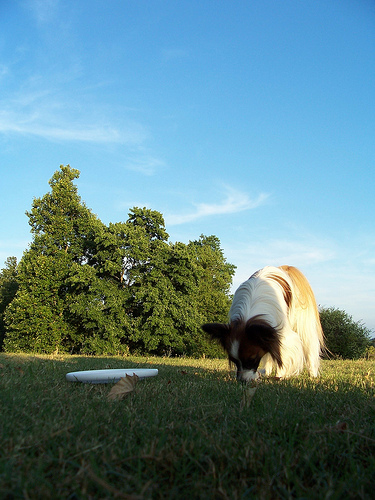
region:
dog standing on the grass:
[199, 263, 344, 402]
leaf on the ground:
[102, 374, 144, 404]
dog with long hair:
[202, 265, 339, 389]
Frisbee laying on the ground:
[56, 356, 165, 386]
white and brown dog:
[202, 255, 335, 386]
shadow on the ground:
[5, 355, 353, 495]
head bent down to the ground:
[196, 304, 286, 381]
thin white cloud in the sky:
[165, 184, 258, 230]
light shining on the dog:
[266, 265, 311, 315]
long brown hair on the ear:
[246, 318, 291, 367]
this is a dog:
[192, 258, 332, 382]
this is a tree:
[0, 180, 132, 364]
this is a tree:
[95, 220, 153, 368]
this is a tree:
[153, 226, 236, 359]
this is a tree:
[314, 295, 367, 367]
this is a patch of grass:
[159, 393, 282, 498]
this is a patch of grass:
[92, 418, 174, 471]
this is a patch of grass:
[307, 394, 348, 466]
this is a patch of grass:
[21, 382, 67, 457]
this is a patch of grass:
[171, 354, 207, 418]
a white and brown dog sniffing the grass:
[199, 264, 329, 384]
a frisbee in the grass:
[63, 367, 171, 385]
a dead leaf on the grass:
[107, 376, 152, 404]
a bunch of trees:
[10, 163, 219, 358]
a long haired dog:
[204, 270, 341, 381]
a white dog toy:
[56, 367, 177, 386]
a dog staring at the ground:
[207, 267, 327, 380]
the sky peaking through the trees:
[105, 246, 163, 291]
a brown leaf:
[101, 375, 146, 401]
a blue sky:
[0, 0, 374, 178]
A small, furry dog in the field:
[211, 254, 346, 398]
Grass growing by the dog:
[167, 396, 305, 475]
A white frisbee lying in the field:
[66, 361, 168, 387]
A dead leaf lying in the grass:
[110, 371, 146, 402]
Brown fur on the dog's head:
[201, 320, 286, 369]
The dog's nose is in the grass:
[228, 363, 259, 384]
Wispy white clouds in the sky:
[6, 97, 264, 225]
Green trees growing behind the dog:
[12, 176, 216, 368]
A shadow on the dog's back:
[232, 275, 281, 337]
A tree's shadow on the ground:
[34, 357, 374, 465]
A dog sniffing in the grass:
[203, 264, 325, 382]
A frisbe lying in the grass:
[53, 365, 169, 389]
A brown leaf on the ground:
[106, 371, 141, 406]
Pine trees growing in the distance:
[7, 180, 199, 360]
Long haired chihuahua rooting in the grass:
[200, 264, 330, 380]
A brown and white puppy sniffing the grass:
[197, 264, 334, 382]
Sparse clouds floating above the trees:
[20, 112, 269, 250]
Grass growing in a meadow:
[185, 405, 345, 484]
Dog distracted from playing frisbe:
[58, 251, 336, 383]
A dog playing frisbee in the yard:
[50, 255, 340, 408]